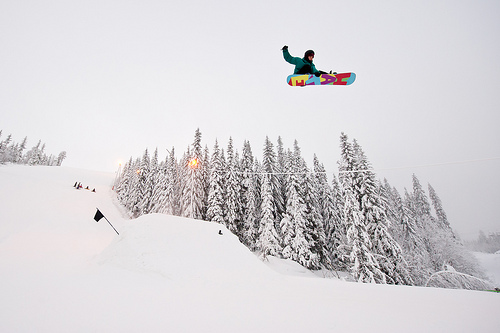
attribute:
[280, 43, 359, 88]
snowboarder — airborne, performing aerial stunt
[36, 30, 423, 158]
clouds — white 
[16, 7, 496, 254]
sky — blue , cloudy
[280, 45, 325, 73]
man — airborne, performing trick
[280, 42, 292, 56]
glove — black 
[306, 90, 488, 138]
clouds — white 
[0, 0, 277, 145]
sky — blue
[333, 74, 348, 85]
letter — red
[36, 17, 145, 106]
clouds — white 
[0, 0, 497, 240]
sky — blue 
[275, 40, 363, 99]
snowboard — airborne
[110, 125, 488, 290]
trees — snow covered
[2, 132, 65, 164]
trees — snow covered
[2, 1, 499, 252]
clouds — white 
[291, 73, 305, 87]
letter — yellow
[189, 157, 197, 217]
light — Illuminated